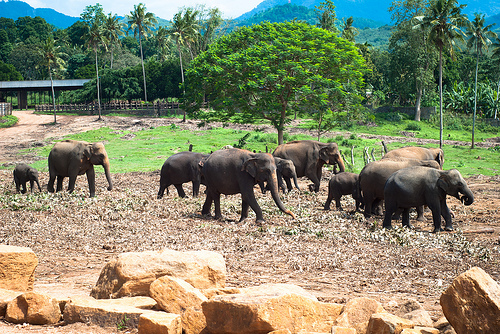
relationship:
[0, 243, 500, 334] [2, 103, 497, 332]
rock in elephant enclosure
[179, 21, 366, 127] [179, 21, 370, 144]
leaves on leaves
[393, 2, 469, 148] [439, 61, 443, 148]
palm tree has trunk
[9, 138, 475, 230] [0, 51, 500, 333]
elephants in elephants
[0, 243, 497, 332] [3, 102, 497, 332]
rock in preserve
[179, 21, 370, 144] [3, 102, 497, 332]
leaves in preserve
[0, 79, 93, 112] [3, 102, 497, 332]
building in preserve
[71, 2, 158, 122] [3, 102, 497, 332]
palm trees in preserve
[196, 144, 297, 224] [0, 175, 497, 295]
elephant on grass